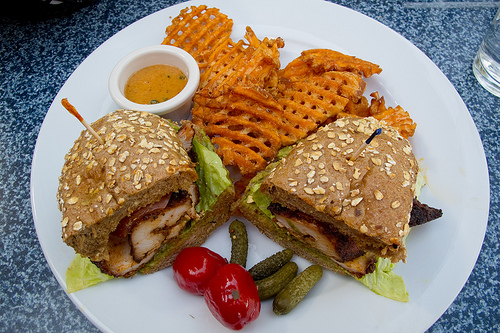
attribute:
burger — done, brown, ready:
[282, 122, 398, 285]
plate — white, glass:
[424, 64, 485, 186]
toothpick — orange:
[50, 94, 109, 142]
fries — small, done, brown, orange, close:
[211, 43, 295, 121]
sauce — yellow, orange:
[111, 53, 217, 126]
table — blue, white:
[14, 26, 51, 59]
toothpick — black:
[369, 123, 381, 162]